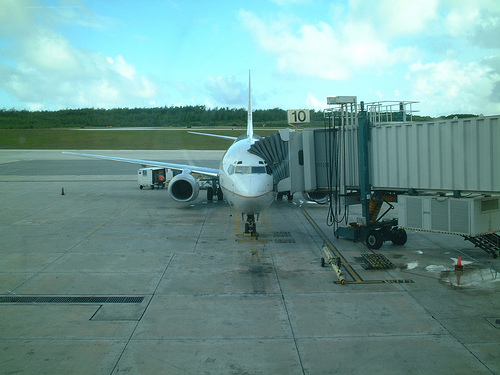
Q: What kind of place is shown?
A: It is an airport.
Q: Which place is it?
A: It is an airport.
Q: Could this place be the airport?
A: Yes, it is the airport.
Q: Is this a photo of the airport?
A: Yes, it is showing the airport.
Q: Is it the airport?
A: Yes, it is the airport.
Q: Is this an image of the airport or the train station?
A: It is showing the airport.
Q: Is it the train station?
A: No, it is the airport.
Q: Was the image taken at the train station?
A: No, the picture was taken in the airport.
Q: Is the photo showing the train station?
A: No, the picture is showing the airport.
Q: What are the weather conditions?
A: It is cloudy.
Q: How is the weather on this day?
A: It is cloudy.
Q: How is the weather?
A: It is cloudy.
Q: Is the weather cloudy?
A: Yes, it is cloudy.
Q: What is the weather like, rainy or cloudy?
A: It is cloudy.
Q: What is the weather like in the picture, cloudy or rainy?
A: It is cloudy.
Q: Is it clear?
A: No, it is cloudy.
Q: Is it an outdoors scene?
A: Yes, it is outdoors.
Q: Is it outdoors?
A: Yes, it is outdoors.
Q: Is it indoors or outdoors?
A: It is outdoors.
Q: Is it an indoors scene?
A: No, it is outdoors.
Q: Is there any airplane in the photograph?
A: Yes, there is an airplane.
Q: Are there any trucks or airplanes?
A: Yes, there is an airplane.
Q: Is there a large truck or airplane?
A: Yes, there is a large airplane.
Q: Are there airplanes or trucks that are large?
A: Yes, the airplane is large.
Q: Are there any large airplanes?
A: Yes, there is a large airplane.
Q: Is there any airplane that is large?
A: Yes, there is an airplane that is large.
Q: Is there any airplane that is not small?
A: Yes, there is a large airplane.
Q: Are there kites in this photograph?
A: No, there are no kites.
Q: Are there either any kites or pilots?
A: No, there are no kites or pilots.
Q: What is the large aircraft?
A: The aircraft is an airplane.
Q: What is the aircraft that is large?
A: The aircraft is an airplane.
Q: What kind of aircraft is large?
A: The aircraft is an airplane.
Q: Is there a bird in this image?
A: No, there are no birds.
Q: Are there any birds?
A: No, there are no birds.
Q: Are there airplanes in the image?
A: Yes, there is an airplane.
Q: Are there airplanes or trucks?
A: Yes, there is an airplane.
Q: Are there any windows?
A: Yes, there are windows.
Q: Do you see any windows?
A: Yes, there are windows.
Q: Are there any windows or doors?
A: Yes, there are windows.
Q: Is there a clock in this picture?
A: No, there are no clocks.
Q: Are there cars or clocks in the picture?
A: No, there are no clocks or cars.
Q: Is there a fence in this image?
A: No, there are no fences.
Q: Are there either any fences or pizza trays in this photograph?
A: No, there are no fences or pizza trays.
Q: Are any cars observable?
A: No, there are no cars.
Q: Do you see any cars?
A: No, there are no cars.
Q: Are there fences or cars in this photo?
A: No, there are no cars or fences.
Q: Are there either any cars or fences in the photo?
A: No, there are no cars or fences.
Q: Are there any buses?
A: No, there are no buses.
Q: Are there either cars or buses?
A: No, there are no buses or cars.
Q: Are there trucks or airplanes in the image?
A: Yes, there is an airplane.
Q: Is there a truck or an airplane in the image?
A: Yes, there is an airplane.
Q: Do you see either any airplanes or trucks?
A: Yes, there is an airplane.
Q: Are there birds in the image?
A: No, there are no birds.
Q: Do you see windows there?
A: Yes, there is a window.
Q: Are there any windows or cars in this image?
A: Yes, there is a window.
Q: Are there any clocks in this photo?
A: No, there are no clocks.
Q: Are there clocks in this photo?
A: No, there are no clocks.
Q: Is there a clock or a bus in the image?
A: No, there are no clocks or buses.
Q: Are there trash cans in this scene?
A: No, there are no trash cans.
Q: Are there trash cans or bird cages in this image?
A: No, there are no trash cans or bird cages.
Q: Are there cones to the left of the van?
A: Yes, there is a cone to the left of the van.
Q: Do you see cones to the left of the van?
A: Yes, there is a cone to the left of the van.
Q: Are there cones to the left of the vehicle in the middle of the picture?
A: Yes, there is a cone to the left of the van.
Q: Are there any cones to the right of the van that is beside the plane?
A: No, the cone is to the left of the van.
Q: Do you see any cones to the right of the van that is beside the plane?
A: No, the cone is to the left of the van.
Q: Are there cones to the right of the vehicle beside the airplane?
A: No, the cone is to the left of the van.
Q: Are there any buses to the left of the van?
A: No, there is a cone to the left of the van.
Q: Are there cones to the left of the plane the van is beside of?
A: Yes, there is a cone to the left of the plane.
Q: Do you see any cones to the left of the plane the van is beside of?
A: Yes, there is a cone to the left of the plane.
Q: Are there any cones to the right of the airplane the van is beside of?
A: No, the cone is to the left of the plane.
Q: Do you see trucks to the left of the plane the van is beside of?
A: No, there is a cone to the left of the airplane.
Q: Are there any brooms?
A: No, there are no brooms.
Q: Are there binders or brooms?
A: No, there are no brooms or binders.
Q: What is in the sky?
A: The clouds are in the sky.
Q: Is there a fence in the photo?
A: No, there are no fences.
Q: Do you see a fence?
A: No, there are no fences.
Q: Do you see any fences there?
A: No, there are no fences.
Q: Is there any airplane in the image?
A: Yes, there is an airplane.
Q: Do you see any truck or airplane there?
A: Yes, there is an airplane.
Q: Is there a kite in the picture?
A: No, there are no kites.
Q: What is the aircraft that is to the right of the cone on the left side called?
A: The aircraft is an airplane.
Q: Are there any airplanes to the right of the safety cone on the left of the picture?
A: Yes, there is an airplane to the right of the traffic cone.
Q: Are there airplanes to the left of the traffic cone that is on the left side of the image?
A: No, the airplane is to the right of the safety cone.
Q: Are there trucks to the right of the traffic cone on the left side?
A: No, there is an airplane to the right of the safety cone.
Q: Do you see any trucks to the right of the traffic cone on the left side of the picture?
A: No, there is an airplane to the right of the safety cone.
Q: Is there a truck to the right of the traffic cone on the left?
A: No, there is an airplane to the right of the safety cone.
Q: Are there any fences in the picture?
A: No, there are no fences.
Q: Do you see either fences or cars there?
A: No, there are no fences or cars.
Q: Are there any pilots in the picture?
A: No, there are no pilots.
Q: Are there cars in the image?
A: No, there are no cars.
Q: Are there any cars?
A: No, there are no cars.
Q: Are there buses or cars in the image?
A: No, there are no cars or buses.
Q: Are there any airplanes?
A: Yes, there is an airplane.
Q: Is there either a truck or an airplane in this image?
A: Yes, there is an airplane.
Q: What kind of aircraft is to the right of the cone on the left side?
A: The aircraft is an airplane.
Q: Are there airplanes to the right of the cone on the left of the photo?
A: Yes, there is an airplane to the right of the safety cone.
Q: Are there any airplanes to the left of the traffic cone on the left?
A: No, the airplane is to the right of the traffic cone.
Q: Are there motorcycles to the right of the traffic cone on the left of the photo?
A: No, there is an airplane to the right of the traffic cone.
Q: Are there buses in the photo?
A: No, there are no buses.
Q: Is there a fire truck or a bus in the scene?
A: No, there are no buses or fire trucks.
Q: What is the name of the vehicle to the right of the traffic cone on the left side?
A: The vehicle is a van.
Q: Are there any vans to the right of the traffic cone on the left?
A: Yes, there is a van to the right of the traffic cone.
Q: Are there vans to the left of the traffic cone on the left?
A: No, the van is to the right of the cone.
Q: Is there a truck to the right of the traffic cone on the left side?
A: No, there is a van to the right of the cone.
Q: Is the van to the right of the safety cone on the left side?
A: Yes, the van is to the right of the traffic cone.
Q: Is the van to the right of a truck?
A: No, the van is to the right of the traffic cone.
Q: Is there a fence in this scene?
A: No, there are no fences.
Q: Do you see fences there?
A: No, there are no fences.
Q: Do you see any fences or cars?
A: No, there are no fences or cars.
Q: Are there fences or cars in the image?
A: No, there are no fences or cars.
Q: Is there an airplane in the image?
A: Yes, there is an airplane.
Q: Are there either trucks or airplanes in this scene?
A: Yes, there is an airplane.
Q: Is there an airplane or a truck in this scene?
A: Yes, there is an airplane.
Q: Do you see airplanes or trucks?
A: Yes, there is an airplane.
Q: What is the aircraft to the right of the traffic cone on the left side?
A: The aircraft is an airplane.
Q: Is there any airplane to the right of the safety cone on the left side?
A: Yes, there is an airplane to the right of the cone.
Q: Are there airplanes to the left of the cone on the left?
A: No, the airplane is to the right of the traffic cone.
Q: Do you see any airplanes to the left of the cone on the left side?
A: No, the airplane is to the right of the traffic cone.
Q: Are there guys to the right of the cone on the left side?
A: No, there is an airplane to the right of the safety cone.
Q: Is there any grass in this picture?
A: Yes, there is grass.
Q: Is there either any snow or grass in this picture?
A: Yes, there is grass.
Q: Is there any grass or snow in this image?
A: Yes, there is grass.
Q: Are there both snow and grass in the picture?
A: No, there is grass but no snow.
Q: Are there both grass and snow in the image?
A: No, there is grass but no snow.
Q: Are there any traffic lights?
A: No, there are no traffic lights.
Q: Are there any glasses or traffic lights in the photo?
A: No, there are no traffic lights or glasses.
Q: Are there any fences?
A: No, there are no fences.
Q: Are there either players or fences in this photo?
A: No, there are no fences or players.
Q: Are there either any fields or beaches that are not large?
A: No, there is a field but it is large.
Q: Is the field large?
A: Yes, the field is large.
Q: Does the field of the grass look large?
A: Yes, the field is large.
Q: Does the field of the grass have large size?
A: Yes, the field is large.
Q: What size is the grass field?
A: The field is large.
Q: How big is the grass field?
A: The field is large.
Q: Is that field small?
A: No, the field is large.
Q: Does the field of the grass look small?
A: No, the field is large.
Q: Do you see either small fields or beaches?
A: No, there is a field but it is large.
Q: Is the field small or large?
A: The field is large.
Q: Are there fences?
A: No, there are no fences.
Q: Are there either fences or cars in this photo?
A: No, there are no fences or cars.